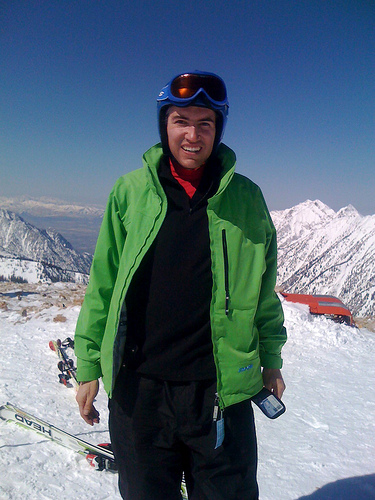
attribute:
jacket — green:
[96, 163, 357, 485]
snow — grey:
[4, 281, 372, 499]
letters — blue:
[222, 356, 285, 402]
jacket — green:
[86, 108, 334, 385]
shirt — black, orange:
[165, 169, 211, 361]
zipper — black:
[222, 223, 235, 316]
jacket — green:
[59, 156, 313, 420]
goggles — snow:
[156, 63, 236, 108]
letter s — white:
[155, 88, 166, 99]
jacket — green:
[74, 141, 287, 410]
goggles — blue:
[156, 67, 229, 117]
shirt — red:
[172, 158, 208, 196]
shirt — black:
[122, 157, 221, 382]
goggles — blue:
[157, 71, 230, 114]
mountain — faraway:
[3, 207, 100, 286]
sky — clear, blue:
[4, 2, 371, 200]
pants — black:
[84, 384, 303, 474]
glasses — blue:
[148, 66, 248, 128]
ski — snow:
[1, 395, 117, 478]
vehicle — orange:
[277, 285, 358, 327]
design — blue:
[236, 358, 256, 376]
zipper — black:
[217, 225, 236, 321]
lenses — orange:
[172, 83, 219, 101]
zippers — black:
[217, 223, 236, 323]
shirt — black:
[119, 169, 234, 391]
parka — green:
[64, 141, 289, 410]